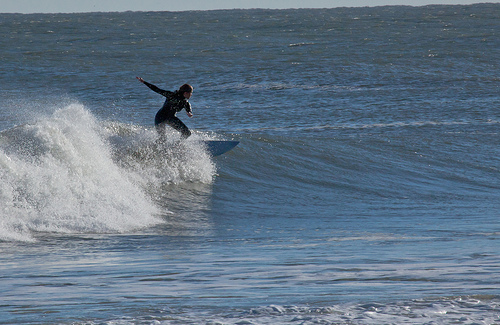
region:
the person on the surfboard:
[120, 70, 245, 165]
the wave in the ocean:
[0, 115, 220, 210]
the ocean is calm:
[5, 15, 490, 145]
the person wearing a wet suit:
[125, 75, 205, 145]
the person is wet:
[120, 70, 205, 150]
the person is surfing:
[120, 70, 255, 165]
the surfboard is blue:
[180, 140, 240, 160]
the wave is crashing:
[5, 110, 130, 255]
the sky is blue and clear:
[5, 1, 237, 6]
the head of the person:
[179, 76, 197, 105]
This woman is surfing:
[129, 63, 211, 155]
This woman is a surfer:
[132, 63, 212, 148]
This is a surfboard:
[157, 125, 242, 163]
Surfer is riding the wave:
[110, 68, 243, 173]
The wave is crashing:
[2, 108, 174, 252]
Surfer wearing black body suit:
[132, 70, 240, 171]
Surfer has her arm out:
[133, 68, 179, 115]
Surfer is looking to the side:
[175, 75, 199, 115]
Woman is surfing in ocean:
[114, 59, 253, 177]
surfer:
[140, 68, 212, 152]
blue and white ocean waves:
[298, 130, 359, 196]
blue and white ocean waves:
[386, 178, 430, 223]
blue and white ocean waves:
[46, 156, 98, 194]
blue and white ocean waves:
[49, 111, 91, 141]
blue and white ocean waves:
[30, 208, 84, 249]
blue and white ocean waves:
[299, 219, 360, 278]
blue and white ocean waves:
[357, 45, 398, 97]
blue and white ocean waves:
[277, 65, 329, 120]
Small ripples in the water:
[28, 262, 53, 293]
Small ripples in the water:
[83, 256, 112, 287]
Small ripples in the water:
[101, 226, 138, 282]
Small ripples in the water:
[135, 257, 174, 300]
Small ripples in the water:
[160, 214, 217, 269]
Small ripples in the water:
[219, 248, 256, 302]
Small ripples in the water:
[260, 183, 292, 254]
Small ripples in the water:
[304, 173, 340, 233]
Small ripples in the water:
[348, 223, 412, 286]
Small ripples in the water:
[300, 106, 400, 169]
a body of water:
[62, 53, 382, 320]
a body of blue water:
[91, 39, 479, 292]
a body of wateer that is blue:
[44, 68, 473, 310]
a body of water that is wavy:
[66, 43, 348, 258]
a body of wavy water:
[83, 41, 449, 299]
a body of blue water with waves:
[111, 37, 421, 301]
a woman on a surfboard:
[132, 79, 381, 301]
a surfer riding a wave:
[157, 52, 327, 267]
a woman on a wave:
[141, 47, 310, 266]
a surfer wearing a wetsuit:
[101, 48, 255, 208]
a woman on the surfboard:
[87, 78, 244, 185]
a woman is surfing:
[82, 30, 217, 155]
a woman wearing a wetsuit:
[113, 73, 183, 139]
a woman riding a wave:
[122, 68, 343, 268]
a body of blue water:
[181, 51, 448, 304]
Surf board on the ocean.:
[169, 140, 239, 157]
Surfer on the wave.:
[0, 98, 498, 243]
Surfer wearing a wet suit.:
[141, 78, 191, 142]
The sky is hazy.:
[0, 0, 498, 13]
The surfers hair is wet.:
[179, 83, 194, 94]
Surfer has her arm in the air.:
[132, 73, 168, 98]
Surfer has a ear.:
[184, 90, 187, 97]